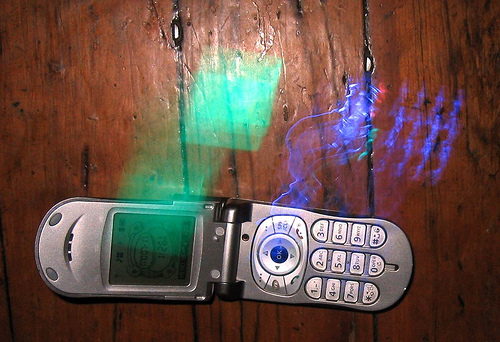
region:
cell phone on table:
[43, 176, 411, 295]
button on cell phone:
[361, 279, 381, 306]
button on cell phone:
[343, 280, 356, 306]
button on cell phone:
[326, 275, 340, 303]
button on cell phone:
[306, 273, 316, 305]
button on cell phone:
[368, 252, 380, 274]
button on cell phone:
[350, 253, 364, 273]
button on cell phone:
[370, 224, 387, 247]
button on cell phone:
[352, 225, 364, 243]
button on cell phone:
[333, 223, 348, 242]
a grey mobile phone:
[157, 213, 361, 303]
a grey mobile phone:
[120, 227, 219, 299]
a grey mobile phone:
[171, 260, 258, 295]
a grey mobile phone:
[181, 236, 258, 282]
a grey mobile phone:
[179, 244, 308, 330]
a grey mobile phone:
[211, 266, 271, 328]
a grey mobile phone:
[227, 217, 317, 333]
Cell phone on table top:
[10, 168, 422, 334]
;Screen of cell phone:
[110, 211, 195, 286]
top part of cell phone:
[22, 182, 215, 307]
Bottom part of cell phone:
[235, 180, 418, 330]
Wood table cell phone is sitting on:
[10, 25, 496, 337]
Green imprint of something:
[86, 35, 286, 256]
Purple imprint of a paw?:
[260, 65, 466, 216]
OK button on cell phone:
[258, 235, 298, 276]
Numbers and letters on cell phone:
[305, 215, 390, 306]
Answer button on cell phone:
[279, 260, 304, 296]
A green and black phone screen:
[88, 196, 201, 301]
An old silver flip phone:
[16, 181, 416, 331]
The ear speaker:
[46, 215, 97, 296]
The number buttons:
[303, 213, 393, 310]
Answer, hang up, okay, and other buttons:
[230, 211, 308, 318]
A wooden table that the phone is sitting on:
[4, 3, 495, 338]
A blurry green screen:
[131, 23, 291, 174]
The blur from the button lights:
[289, 49, 471, 248]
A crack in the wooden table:
[135, 13, 222, 150]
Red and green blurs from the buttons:
[356, 75, 391, 170]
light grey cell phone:
[62, 157, 430, 317]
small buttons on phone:
[309, 221, 389, 317]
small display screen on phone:
[102, 186, 177, 325]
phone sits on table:
[44, 178, 412, 333]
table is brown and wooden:
[61, 25, 420, 304]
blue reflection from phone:
[276, 77, 434, 190]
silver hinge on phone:
[214, 185, 261, 320]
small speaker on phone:
[45, 217, 97, 310]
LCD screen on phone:
[115, 196, 202, 308]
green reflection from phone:
[172, 88, 297, 213]